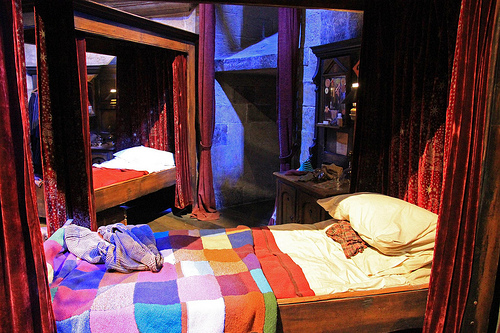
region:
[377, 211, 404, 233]
Pillow on the bed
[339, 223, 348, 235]
A piece of cloth next to the pillow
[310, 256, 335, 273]
A sheet spread out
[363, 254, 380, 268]
A pillow beneath another pillow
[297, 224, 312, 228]
Shadow on the sheet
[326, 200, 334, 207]
Shadow on the top pillow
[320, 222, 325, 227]
Shadow on the pillow below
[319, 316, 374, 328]
Wooden bed side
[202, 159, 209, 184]
A drape hanging down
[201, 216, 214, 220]
Drape touching the floor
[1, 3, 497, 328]
bed with red drapes on a canopy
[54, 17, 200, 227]
bed with red drapes on a canopy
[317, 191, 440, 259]
pillow in a tan case on a bed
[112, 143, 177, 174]
pillow in a white case on a bed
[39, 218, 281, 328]
multi colored bedspread on a single bed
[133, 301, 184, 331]
blue square on a bedspread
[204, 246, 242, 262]
orange square on a bedspread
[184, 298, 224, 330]
white square on a bedspread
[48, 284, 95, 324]
pink square on a bedspread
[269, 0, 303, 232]
long purple drapes with a band around them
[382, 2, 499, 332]
drawn red velvet curtains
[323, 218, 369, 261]
plaid pajamas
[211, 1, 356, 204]
concrete block entrance way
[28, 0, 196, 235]
alcove with single bed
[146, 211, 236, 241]
moss and khaki colored rug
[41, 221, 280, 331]
multi-colored quilt bed covering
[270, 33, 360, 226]
old wooden hutch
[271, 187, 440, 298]
wrinkled pillow and top sheet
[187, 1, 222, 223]
red curtains tied with a sash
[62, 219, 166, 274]
robe lying on bed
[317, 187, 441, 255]
off white colored pillow on a bed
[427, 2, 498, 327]
long maroon colored velour curtain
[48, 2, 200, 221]
bed and curtains inside of wooden bed frame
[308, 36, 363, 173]
dark wooden cabinet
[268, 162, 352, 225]
small wooden nightstand next to bed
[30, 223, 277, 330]
multicolored blanket on bed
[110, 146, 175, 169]
white bed pillow on bed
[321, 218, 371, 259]
red plaid pajamas on bed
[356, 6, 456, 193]
long red curtain hanging behind bed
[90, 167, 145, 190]
red blanket on bed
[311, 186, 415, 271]
the pillow on a bed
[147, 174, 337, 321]
a blanket on a bed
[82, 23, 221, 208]
mirrors in a room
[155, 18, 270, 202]
curtains in a room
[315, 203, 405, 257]
a pillow in a room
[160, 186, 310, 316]
a blanket in a room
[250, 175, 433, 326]
a bed in a room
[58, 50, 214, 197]
a mirror in a room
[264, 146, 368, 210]
a table in a room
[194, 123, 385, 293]
a bed near a table